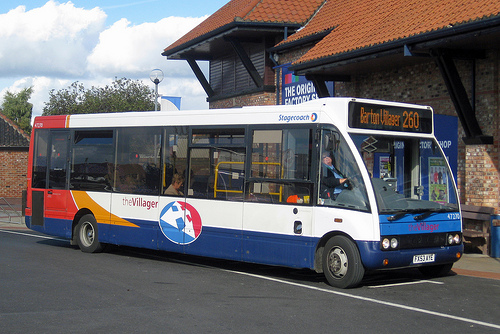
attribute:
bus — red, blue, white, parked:
[26, 96, 466, 288]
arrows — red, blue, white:
[159, 200, 206, 245]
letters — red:
[406, 221, 440, 232]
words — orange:
[356, 104, 423, 132]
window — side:
[164, 127, 186, 196]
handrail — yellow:
[209, 159, 286, 201]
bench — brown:
[462, 206, 497, 253]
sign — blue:
[278, 63, 317, 103]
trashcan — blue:
[492, 215, 499, 258]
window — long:
[354, 131, 457, 215]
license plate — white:
[412, 254, 437, 264]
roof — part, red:
[162, 2, 499, 66]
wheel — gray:
[74, 214, 99, 252]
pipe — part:
[267, 53, 284, 107]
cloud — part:
[3, 7, 108, 78]